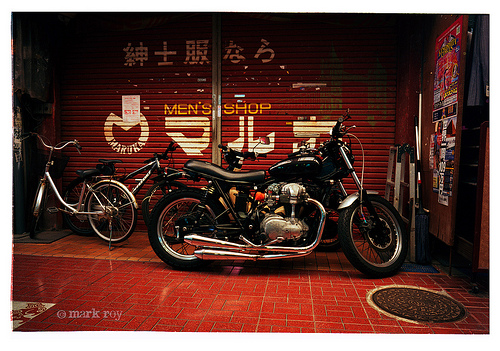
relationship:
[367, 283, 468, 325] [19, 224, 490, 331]
man hole cover on ground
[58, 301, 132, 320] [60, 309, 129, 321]
name in white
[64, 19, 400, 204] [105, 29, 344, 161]
door with writing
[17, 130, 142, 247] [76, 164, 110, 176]
bicycle with seat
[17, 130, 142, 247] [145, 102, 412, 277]
bicycle behind motorcycle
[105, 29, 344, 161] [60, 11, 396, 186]
writing on wall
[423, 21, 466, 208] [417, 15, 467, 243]
pictures on wall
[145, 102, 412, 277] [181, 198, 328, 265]
motorcycle has muffler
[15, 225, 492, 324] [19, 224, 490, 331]
bricks on ground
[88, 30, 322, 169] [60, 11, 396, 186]
sign on wall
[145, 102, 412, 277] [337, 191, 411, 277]
motorcycle has tire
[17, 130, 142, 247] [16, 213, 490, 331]
bicycle parked on floor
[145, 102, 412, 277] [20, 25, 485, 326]
motorcycle parked in garage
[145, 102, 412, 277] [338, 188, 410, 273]
motorcycle has wheel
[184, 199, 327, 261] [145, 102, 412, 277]
pipes on motorcycle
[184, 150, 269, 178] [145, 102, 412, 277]
seat on motorcycle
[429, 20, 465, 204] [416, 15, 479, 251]
advertising on garage door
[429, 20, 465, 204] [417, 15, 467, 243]
advertising on wall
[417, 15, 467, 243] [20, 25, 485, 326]
wall in garage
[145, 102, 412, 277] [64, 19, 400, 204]
motorcycle in front of door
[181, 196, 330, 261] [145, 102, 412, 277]
exhaust pipes on motorcycle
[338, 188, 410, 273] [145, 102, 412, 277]
wheel on motorcycle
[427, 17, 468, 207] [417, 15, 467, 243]
posters on wall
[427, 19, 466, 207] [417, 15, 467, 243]
stickers on wall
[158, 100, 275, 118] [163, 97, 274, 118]
lettering reading men's shop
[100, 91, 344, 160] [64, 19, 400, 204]
symbol on door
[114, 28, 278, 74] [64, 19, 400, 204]
symbols on door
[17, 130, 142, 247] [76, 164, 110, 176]
bicycle has seat